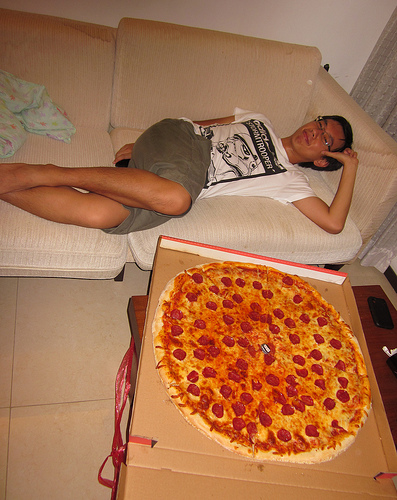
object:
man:
[0, 106, 359, 234]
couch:
[109, 17, 397, 271]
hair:
[298, 114, 353, 171]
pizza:
[152, 260, 373, 464]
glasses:
[314, 115, 330, 152]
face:
[291, 118, 345, 160]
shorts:
[100, 117, 212, 235]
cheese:
[197, 377, 263, 428]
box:
[113, 234, 397, 499]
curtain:
[352, 8, 397, 274]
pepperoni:
[208, 346, 219, 357]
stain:
[257, 463, 265, 472]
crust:
[155, 272, 194, 347]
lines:
[98, 336, 136, 500]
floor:
[0, 263, 148, 500]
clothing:
[178, 106, 318, 207]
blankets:
[0, 70, 77, 158]